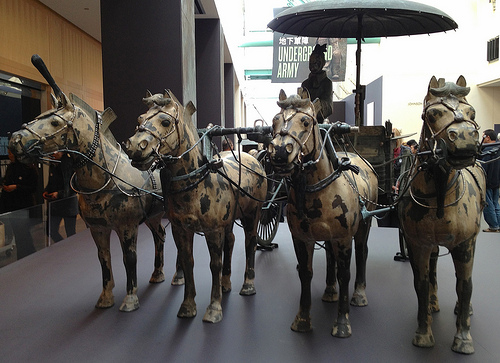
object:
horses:
[44, 87, 499, 331]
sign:
[274, 25, 356, 80]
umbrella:
[273, 8, 459, 36]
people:
[396, 130, 499, 201]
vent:
[479, 35, 499, 57]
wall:
[424, 28, 499, 156]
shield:
[0, 197, 82, 242]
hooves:
[95, 272, 474, 362]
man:
[302, 47, 328, 104]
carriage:
[229, 120, 391, 214]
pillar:
[103, 3, 195, 151]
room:
[6, 3, 484, 285]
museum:
[6, 3, 496, 323]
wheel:
[236, 185, 293, 253]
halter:
[29, 54, 77, 106]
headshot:
[16, 88, 119, 200]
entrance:
[5, 76, 54, 258]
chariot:
[259, 119, 379, 201]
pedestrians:
[0, 150, 80, 233]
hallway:
[14, 66, 104, 223]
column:
[104, 2, 200, 171]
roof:
[39, 3, 499, 114]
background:
[12, 13, 464, 200]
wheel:
[382, 185, 416, 253]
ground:
[37, 224, 461, 362]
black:
[197, 191, 212, 213]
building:
[8, 7, 498, 199]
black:
[269, 6, 461, 40]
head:
[423, 80, 480, 181]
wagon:
[286, 95, 419, 232]